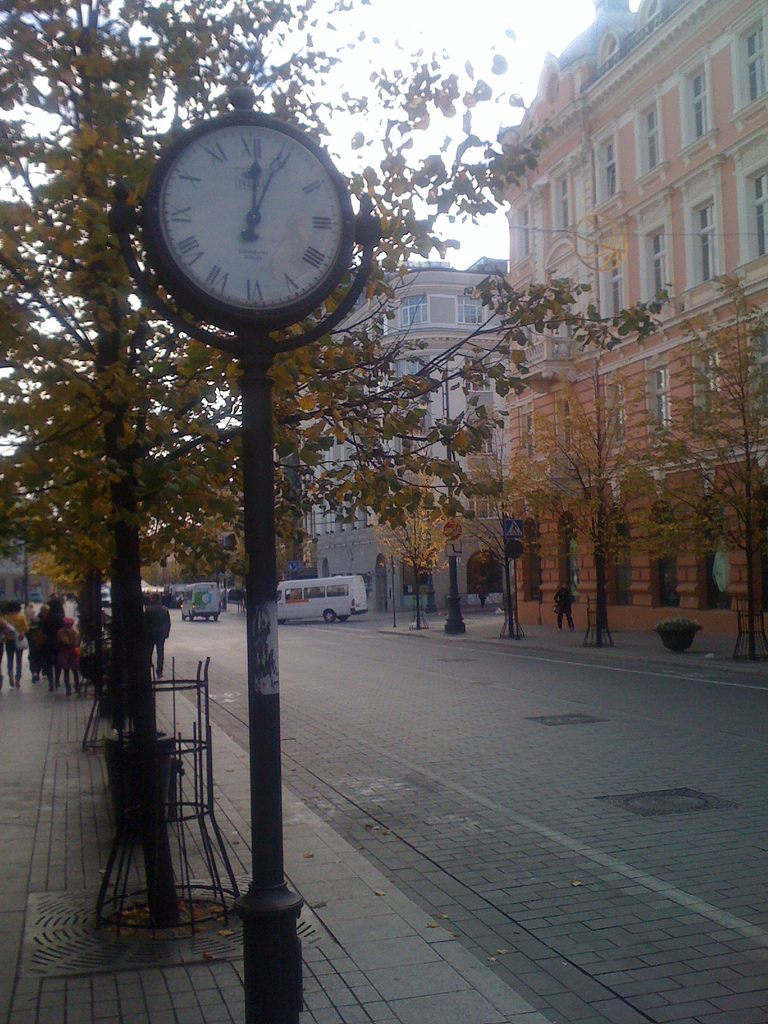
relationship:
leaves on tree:
[579, 296, 661, 350] [378, 342, 526, 646]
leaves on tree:
[67, 42, 163, 101] [146, 411, 282, 603]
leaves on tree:
[71, 41, 128, 92] [4, 87, 517, 913]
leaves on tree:
[159, 467, 228, 519] [4, 87, 517, 913]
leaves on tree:
[396, 64, 483, 125] [375, 406, 509, 643]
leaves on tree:
[331, 460, 420, 520] [643, 428, 765, 662]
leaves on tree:
[44, 516, 115, 566] [506, 384, 701, 652]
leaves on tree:
[151, 14, 221, 78] [4, 9, 439, 936]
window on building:
[679, 189, 728, 288] [467, 4, 763, 663]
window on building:
[633, 216, 679, 309] [467, 4, 763, 663]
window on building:
[637, 216, 674, 309] [502, 88, 703, 230]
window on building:
[587, 227, 634, 324] [501, 107, 765, 458]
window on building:
[594, 132, 622, 208] [467, 4, 763, 663]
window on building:
[680, 83, 722, 141] [467, 4, 763, 663]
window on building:
[637, 216, 674, 309] [467, 4, 763, 663]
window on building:
[576, 137, 630, 200] [467, 4, 763, 663]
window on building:
[526, 177, 587, 243] [467, 4, 763, 663]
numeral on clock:
[226, 123, 276, 169] [168, 93, 347, 325]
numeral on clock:
[239, 137, 261, 159] [134, 107, 360, 327]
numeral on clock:
[239, 137, 261, 159] [148, 114, 363, 330]